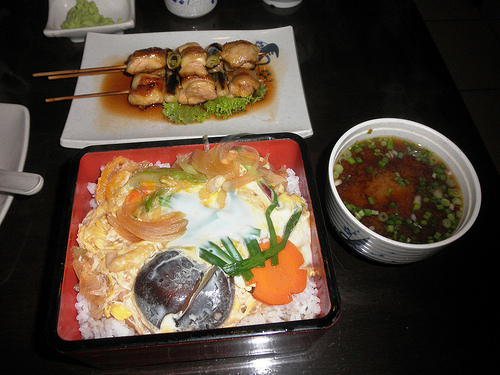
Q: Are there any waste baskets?
A: No, there are no waste baskets.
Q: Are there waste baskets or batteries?
A: No, there are no waste baskets or batteries.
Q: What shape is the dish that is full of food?
A: The dish is square.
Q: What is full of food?
A: The dish is full of food.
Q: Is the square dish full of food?
A: Yes, the dish is full of food.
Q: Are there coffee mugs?
A: No, there are no coffee mugs.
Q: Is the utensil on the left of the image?
A: Yes, the utensil is on the left of the image.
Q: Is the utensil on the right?
A: No, the utensil is on the left of the image.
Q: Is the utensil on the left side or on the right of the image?
A: The utensil is on the left of the image.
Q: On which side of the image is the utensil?
A: The utensil is on the left of the image.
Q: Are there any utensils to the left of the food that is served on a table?
A: Yes, there is a utensil to the left of the food.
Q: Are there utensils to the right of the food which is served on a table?
A: No, the utensil is to the left of the food.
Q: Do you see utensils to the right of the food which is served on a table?
A: No, the utensil is to the left of the food.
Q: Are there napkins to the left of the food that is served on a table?
A: No, there is a utensil to the left of the food.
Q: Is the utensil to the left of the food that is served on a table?
A: Yes, the utensil is to the left of the food.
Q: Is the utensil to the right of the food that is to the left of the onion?
A: No, the utensil is to the left of the food.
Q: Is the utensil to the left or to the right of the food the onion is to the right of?
A: The utensil is to the left of the food.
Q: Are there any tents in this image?
A: No, there are no tents.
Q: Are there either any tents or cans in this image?
A: No, there are no tents or cans.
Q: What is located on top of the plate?
A: The fish is on top of the plate.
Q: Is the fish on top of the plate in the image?
A: Yes, the fish is on top of the plate.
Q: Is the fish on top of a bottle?
A: No, the fish is on top of the plate.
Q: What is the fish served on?
A: The fish is served on a stick.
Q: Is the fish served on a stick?
A: Yes, the fish is served on a stick.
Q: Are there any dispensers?
A: No, there are no dispensers.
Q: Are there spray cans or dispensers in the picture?
A: No, there are no dispensers or spray cans.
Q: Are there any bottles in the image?
A: No, there are no bottles.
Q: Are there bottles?
A: No, there are no bottles.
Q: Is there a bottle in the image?
A: No, there are no bottles.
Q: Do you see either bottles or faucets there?
A: No, there are no bottles or faucets.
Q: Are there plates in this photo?
A: Yes, there is a plate.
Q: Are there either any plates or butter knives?
A: Yes, there is a plate.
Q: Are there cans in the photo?
A: No, there are no cans.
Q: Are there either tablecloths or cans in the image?
A: No, there are no cans or tablecloths.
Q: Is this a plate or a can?
A: This is a plate.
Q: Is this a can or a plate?
A: This is a plate.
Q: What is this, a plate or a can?
A: This is a plate.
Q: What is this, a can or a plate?
A: This is a plate.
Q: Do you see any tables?
A: Yes, there is a table.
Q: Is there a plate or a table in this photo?
A: Yes, there is a table.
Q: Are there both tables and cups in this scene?
A: No, there is a table but no cups.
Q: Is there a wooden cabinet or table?
A: Yes, there is a wood table.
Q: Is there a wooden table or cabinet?
A: Yes, there is a wood table.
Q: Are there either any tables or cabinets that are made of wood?
A: Yes, the table is made of wood.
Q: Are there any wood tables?
A: Yes, there is a wood table.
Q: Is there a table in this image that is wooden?
A: Yes, there is a table that is wooden.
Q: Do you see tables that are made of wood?
A: Yes, there is a table that is made of wood.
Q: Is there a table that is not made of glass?
A: Yes, there is a table that is made of wood.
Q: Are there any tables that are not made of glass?
A: Yes, there is a table that is made of wood.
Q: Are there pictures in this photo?
A: No, there are no pictures.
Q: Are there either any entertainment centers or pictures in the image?
A: No, there are no pictures or entertainment centers.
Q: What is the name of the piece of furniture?
A: The piece of furniture is a table.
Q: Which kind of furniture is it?
A: The piece of furniture is a table.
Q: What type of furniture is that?
A: This is a table.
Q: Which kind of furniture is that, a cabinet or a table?
A: This is a table.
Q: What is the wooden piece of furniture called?
A: The piece of furniture is a table.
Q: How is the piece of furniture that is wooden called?
A: The piece of furniture is a table.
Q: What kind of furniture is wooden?
A: The furniture is a table.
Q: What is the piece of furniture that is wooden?
A: The piece of furniture is a table.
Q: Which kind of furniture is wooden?
A: The furniture is a table.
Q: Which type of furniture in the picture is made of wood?
A: The furniture is a table.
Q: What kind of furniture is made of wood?
A: The furniture is a table.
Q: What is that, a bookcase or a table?
A: That is a table.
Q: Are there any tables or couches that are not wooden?
A: No, there is a table but it is wooden.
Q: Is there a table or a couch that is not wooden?
A: No, there is a table but it is wooden.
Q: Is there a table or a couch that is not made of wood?
A: No, there is a table but it is made of wood.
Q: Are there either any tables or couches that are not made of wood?
A: No, there is a table but it is made of wood.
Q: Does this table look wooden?
A: Yes, the table is wooden.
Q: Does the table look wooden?
A: Yes, the table is wooden.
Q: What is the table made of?
A: The table is made of wood.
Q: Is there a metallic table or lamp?
A: No, there is a table but it is wooden.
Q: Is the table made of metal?
A: No, the table is made of wood.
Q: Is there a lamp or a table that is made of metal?
A: No, there is a table but it is made of wood.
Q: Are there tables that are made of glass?
A: No, there is a table but it is made of wood.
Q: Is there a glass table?
A: No, there is a table but it is made of wood.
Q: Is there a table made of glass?
A: No, there is a table but it is made of wood.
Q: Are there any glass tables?
A: No, there is a table but it is made of wood.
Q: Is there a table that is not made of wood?
A: No, there is a table but it is made of wood.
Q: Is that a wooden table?
A: Yes, that is a wooden table.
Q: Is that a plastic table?
A: No, that is a wooden table.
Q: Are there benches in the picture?
A: No, there are no benches.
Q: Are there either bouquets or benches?
A: No, there are no benches or bouquets.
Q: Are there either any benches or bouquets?
A: No, there are no benches or bouquets.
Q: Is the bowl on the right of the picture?
A: Yes, the bowl is on the right of the image.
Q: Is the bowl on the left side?
A: No, the bowl is on the right of the image.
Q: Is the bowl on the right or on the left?
A: The bowl is on the right of the image.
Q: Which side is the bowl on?
A: The bowl is on the right of the image.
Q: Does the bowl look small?
A: Yes, the bowl is small.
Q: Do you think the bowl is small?
A: Yes, the bowl is small.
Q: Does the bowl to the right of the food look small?
A: Yes, the bowl is small.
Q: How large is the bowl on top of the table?
A: The bowl is small.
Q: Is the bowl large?
A: No, the bowl is small.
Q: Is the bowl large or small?
A: The bowl is small.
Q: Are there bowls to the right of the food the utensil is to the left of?
A: Yes, there is a bowl to the right of the food.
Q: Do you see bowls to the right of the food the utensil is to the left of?
A: Yes, there is a bowl to the right of the food.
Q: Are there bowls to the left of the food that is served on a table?
A: No, the bowl is to the right of the food.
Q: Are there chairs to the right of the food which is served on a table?
A: No, there is a bowl to the right of the food.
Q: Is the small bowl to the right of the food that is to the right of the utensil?
A: Yes, the bowl is to the right of the food.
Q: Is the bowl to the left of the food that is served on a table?
A: No, the bowl is to the right of the food.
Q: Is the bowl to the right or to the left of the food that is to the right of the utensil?
A: The bowl is to the right of the food.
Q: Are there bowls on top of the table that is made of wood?
A: Yes, there is a bowl on top of the table.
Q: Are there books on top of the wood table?
A: No, there is a bowl on top of the table.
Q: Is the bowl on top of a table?
A: Yes, the bowl is on top of a table.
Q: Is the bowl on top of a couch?
A: No, the bowl is on top of a table.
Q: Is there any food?
A: Yes, there is food.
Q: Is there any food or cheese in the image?
A: Yes, there is food.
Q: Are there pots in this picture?
A: No, there are no pots.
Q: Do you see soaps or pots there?
A: No, there are no pots or soaps.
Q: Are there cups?
A: No, there are no cups.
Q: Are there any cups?
A: No, there are no cups.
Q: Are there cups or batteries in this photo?
A: No, there are no cups or batteries.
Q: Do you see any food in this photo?
A: Yes, there is food.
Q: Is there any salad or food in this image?
A: Yes, there is food.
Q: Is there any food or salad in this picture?
A: Yes, there is food.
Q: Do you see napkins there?
A: No, there are no napkins.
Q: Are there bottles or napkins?
A: No, there are no napkins or bottles.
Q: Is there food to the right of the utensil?
A: Yes, there is food to the right of the utensil.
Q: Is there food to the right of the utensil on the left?
A: Yes, there is food to the right of the utensil.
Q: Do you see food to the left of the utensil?
A: No, the food is to the right of the utensil.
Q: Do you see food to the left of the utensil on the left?
A: No, the food is to the right of the utensil.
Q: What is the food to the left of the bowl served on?
A: The food is served on a table.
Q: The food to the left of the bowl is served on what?
A: The food is served on a table.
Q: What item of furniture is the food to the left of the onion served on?
A: The food is served on a table.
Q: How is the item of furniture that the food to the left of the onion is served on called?
A: The piece of furniture is a table.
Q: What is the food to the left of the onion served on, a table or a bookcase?
A: The food is served on a table.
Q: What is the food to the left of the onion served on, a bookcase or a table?
A: The food is served on a table.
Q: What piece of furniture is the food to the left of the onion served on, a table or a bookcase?
A: The food is served on a table.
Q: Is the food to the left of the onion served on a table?
A: Yes, the food is served on a table.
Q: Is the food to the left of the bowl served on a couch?
A: No, the food is served on a table.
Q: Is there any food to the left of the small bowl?
A: Yes, there is food to the left of the bowl.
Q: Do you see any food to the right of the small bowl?
A: No, the food is to the left of the bowl.